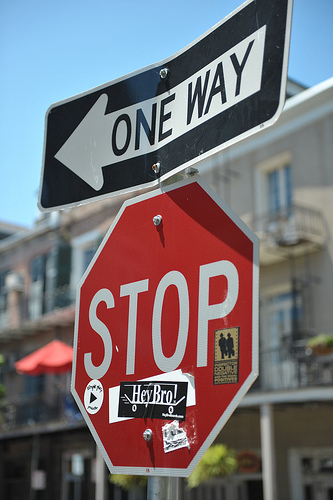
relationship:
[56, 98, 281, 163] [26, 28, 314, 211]
arrow on sign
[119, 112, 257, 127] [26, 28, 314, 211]
words on sign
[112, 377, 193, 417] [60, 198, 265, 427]
sticker on sign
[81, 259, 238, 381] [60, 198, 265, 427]
stop on sign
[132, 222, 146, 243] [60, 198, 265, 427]
light hitting sign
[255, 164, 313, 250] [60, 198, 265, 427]
window behind sign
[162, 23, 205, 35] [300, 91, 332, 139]
sky above building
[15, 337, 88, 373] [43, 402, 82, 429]
red umbrella on balcony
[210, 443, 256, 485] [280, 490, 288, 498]
hanging flowers on street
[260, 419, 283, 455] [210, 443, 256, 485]
white pole by hanging flowers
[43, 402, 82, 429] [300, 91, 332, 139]
balcony of building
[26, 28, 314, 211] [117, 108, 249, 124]
sign says one way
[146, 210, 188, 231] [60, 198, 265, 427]
bolt on sign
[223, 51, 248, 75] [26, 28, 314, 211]
black letters on sign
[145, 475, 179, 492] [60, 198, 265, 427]
pole holding signs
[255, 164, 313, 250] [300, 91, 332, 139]
window of building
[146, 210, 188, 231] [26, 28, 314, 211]
bolt on sign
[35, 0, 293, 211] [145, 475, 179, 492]
sign on pole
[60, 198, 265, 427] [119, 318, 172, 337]
sign says stop